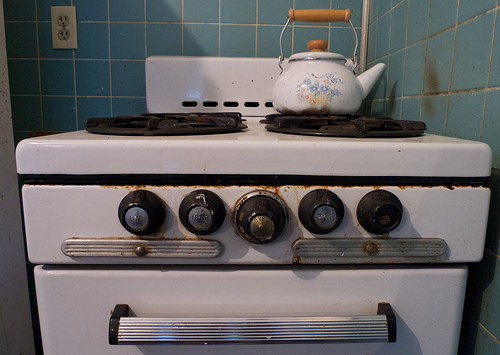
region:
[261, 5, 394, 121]
A white tea pot on stove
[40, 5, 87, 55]
a white power outlet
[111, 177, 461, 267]
five black knobs on front of stove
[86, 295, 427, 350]
a silver handle on oven door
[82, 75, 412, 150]
black grates on top of stove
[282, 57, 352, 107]
a flower design on teapot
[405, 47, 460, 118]
black burn mark on wall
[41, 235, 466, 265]
two silver bars under knobs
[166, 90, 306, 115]
several vent holes on back of stove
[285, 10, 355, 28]
wooden handle on teapot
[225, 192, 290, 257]
The center oven knob.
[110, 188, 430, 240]
The panel of black knobs on the stove.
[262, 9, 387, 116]
The tea kettle on top of the stove.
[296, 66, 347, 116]
The flower design on the tea kettle.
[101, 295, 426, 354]
The silver oven handle.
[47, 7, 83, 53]
The electrical socket on the wall.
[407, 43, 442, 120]
The two brown stains on the right side wall.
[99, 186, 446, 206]
The rust stains above the panel of knobs on the stove.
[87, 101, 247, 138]
The black burners on the left side of the stove.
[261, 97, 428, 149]
The black burners on the right side of the stove.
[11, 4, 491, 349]
Old white rusty stove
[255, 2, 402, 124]
Tea kettle with wood handle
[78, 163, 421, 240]
Five knobs on a stove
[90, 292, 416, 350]
Silver and black over door handle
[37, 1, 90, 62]
Outlet on a wall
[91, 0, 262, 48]
Blue tile wall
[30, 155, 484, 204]
Rust around the knobs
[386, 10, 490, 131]
Dirty blue tile wall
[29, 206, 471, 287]
Two metal brackets on a stove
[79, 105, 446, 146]
Burners on a stove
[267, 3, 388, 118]
White tea kettle sitting on top of stove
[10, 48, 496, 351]
White stove sitting in the corner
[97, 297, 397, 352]
Oven door handle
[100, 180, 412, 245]
Control knobs on white stove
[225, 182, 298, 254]
Control knob for the oven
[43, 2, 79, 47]
White outlet in aqua colored wall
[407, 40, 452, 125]
Burned spot on aqua colored wall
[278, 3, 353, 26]
Wood handle of teacup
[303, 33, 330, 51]
Wood knob for tea top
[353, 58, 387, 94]
White tea kettle sprout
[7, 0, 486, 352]
an old stove oven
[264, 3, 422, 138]
a teapot on top of the stove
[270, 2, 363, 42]
the handle of the teapot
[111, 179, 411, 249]
control dials of the stove oven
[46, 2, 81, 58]
a plug socket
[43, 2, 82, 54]
a white plug socket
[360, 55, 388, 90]
the spout of the teapot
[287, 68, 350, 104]
the flower print on the teapot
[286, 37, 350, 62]
the lid of the teapot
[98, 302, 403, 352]
the handle of the oven to open and close the door